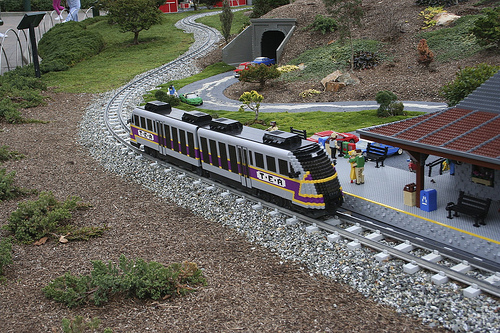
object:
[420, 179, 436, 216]
recycle bin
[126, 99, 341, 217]
model train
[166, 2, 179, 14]
door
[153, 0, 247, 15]
building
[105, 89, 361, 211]
train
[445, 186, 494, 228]
bench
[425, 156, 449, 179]
bench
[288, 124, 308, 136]
bench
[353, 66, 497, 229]
station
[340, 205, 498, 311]
tracks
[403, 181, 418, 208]
trash can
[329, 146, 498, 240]
platform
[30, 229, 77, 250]
leaves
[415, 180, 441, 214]
trash can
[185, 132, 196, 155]
window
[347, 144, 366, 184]
person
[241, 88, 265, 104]
leaves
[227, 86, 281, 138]
tree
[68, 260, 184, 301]
bush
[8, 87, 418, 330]
brown dirt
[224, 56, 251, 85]
car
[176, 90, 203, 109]
car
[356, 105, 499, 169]
overhang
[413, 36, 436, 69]
bush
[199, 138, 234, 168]
window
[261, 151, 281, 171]
window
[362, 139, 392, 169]
bench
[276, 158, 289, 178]
window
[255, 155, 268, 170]
window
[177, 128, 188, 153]
window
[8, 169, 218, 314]
ground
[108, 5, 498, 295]
track